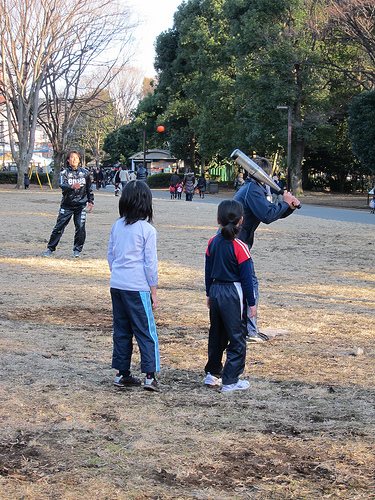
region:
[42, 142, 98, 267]
a parent standing in a field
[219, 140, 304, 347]
a man holding a baseball bat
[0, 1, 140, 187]
trees with no leaves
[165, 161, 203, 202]
woman walks with her children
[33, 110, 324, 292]
many people on ground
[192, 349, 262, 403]
shoes of the person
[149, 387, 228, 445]
ground under the people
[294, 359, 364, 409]
shadow on the ground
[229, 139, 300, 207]
bat in person's hand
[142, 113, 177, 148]
ball in the air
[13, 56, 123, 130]
branches of the trees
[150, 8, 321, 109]
trees in the distance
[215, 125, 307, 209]
person waiting to hit ball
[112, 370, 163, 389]
The child is wearing blue and black sneakers.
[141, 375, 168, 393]
The right foot of the child.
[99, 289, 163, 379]
The pants has a turquoise stripe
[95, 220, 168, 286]
The person has on a long sleeved shirt.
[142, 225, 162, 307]
The right hand of the person.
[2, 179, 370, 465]
The field is made of dirt.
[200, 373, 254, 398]
The person has on white sneakers.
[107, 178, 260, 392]
Two girls standing behind batter.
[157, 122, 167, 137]
Ball traveling through the air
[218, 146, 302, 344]
Boy holding a baseball bat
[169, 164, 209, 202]
People walking on the path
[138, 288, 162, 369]
Stripe down leg of girl's pants.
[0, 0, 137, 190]
Bare trees in the park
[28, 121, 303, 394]
Girls watching two boys play baseball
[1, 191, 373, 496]
Brownish grass in the park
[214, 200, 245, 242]
Girl's black hair styled in a ponytail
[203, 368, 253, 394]
The young child is wearing white sneakers.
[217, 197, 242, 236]
The boy has his hair in a ponytail.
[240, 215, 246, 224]
The right ear of the boy.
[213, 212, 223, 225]
The left ear of the boy.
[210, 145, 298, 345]
The person is holding a bat.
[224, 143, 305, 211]
The bat is made of metal.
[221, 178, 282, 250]
The person is wearing a blue shirt.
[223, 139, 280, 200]
the bat is silver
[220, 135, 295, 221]
the bat is silver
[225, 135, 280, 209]
the bat is silver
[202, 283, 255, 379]
A pair of dark blue pants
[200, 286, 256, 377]
The dark blue pants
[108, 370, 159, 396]
the black sneakers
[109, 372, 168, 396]
A pair of black sneakers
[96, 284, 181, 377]
The pants with a light blue stripe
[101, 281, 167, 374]
A blue striped pant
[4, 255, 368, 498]
The dirt patch field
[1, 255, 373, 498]
A dirty field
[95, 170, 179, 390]
The child to the left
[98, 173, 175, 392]
A child to the left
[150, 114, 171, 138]
A round orange ball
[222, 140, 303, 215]
A silver metal baseball bat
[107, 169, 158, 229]
Kid has long black hair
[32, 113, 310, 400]
Group of people playing baseball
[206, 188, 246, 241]
Black hair in a ponytail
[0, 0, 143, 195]
Two big trees with no leaves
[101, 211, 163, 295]
A long sleeved light blue shirt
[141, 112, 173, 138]
A ball in the air